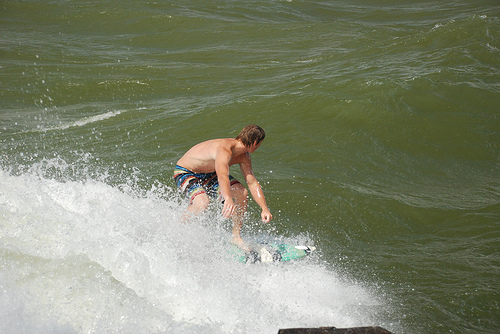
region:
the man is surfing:
[28, 46, 366, 291]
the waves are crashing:
[85, 158, 232, 288]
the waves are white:
[65, 183, 212, 307]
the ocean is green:
[131, 38, 432, 139]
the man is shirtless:
[200, 95, 275, 179]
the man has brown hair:
[197, 112, 321, 186]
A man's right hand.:
[219, 199, 236, 219]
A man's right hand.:
[260, 209, 272, 224]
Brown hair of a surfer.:
[236, 122, 266, 147]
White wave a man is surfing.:
[0, 162, 382, 333]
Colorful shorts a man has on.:
[172, 163, 242, 207]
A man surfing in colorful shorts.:
[171, 122, 271, 252]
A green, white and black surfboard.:
[212, 234, 315, 264]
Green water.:
[2, 4, 498, 331]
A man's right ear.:
[250, 138, 257, 145]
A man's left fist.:
[259, 209, 272, 225]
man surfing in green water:
[171, 118, 281, 233]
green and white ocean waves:
[357, 41, 437, 111]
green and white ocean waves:
[304, 219, 395, 303]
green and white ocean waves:
[118, 241, 183, 291]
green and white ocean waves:
[45, 159, 119, 233]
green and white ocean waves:
[57, 235, 139, 290]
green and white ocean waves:
[47, 42, 92, 87]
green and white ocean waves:
[277, 25, 348, 82]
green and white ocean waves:
[344, 111, 419, 186]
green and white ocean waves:
[50, 28, 122, 83]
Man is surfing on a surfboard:
[171, 125, 314, 260]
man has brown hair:
[240, 125, 264, 147]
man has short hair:
[236, 123, 266, 148]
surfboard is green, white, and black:
[203, 239, 313, 266]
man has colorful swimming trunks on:
[171, 164, 238, 195]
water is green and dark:
[0, 0, 499, 332]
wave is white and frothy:
[2, 167, 397, 332]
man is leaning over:
[169, 123, 276, 250]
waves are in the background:
[0, 0, 498, 203]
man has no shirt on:
[173, 135, 252, 172]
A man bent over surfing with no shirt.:
[171, 124, 271, 249]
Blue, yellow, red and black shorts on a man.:
[173, 163, 240, 207]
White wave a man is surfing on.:
[2, 166, 388, 332]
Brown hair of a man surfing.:
[237, 122, 266, 148]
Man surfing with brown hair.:
[170, 124, 271, 251]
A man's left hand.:
[258, 207, 274, 222]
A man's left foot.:
[229, 231, 251, 253]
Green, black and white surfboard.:
[221, 232, 316, 265]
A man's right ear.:
[252, 137, 257, 149]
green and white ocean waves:
[321, 32, 356, 64]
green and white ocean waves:
[301, 261, 358, 298]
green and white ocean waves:
[167, 262, 211, 296]